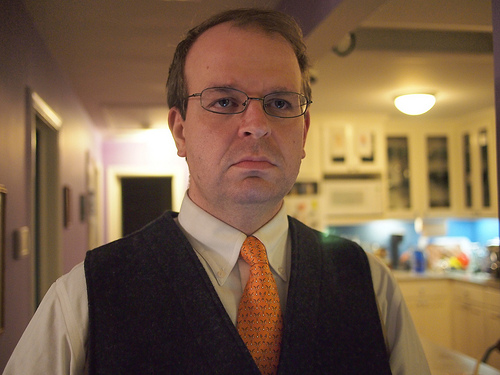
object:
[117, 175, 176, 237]
doorway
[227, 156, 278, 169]
mouth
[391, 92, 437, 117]
light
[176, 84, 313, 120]
glasses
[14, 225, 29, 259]
switch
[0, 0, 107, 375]
wall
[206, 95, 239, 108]
eye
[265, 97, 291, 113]
eye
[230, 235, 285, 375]
tie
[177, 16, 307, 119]
hairline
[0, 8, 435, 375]
guy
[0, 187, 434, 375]
collard shirt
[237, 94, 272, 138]
nose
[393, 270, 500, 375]
kitchen counterop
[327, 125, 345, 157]
picture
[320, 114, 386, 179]
cabinets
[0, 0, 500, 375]
kitchen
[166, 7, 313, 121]
hair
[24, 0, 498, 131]
ceiling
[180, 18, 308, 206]
face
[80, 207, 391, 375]
sweater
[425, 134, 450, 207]
glass